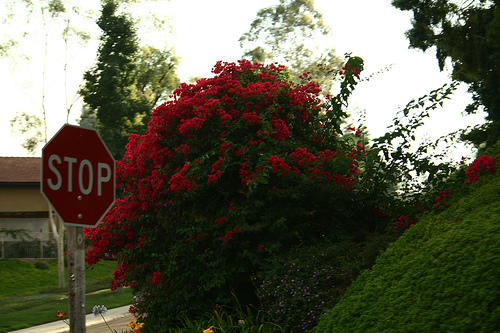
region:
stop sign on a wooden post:
[28, 114, 127, 331]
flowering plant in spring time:
[82, 43, 392, 331]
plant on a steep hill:
[90, 51, 492, 331]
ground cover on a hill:
[315, 173, 499, 331]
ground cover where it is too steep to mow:
[320, 168, 498, 328]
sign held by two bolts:
[30, 105, 127, 251]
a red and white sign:
[35, 107, 131, 327]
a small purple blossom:
[218, 235, 353, 331]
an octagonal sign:
[7, 96, 142, 331]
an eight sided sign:
[27, 102, 134, 264]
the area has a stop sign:
[28, 99, 150, 273]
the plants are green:
[337, 165, 495, 331]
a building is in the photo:
[4, 150, 61, 268]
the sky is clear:
[8, 5, 482, 79]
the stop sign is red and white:
[21, 110, 142, 256]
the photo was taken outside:
[9, 4, 487, 329]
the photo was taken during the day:
[3, 4, 494, 327]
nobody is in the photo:
[4, 7, 494, 328]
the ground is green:
[5, 257, 137, 330]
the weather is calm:
[6, 10, 485, 330]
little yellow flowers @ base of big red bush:
[122, 313, 224, 332]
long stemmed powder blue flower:
[87, 298, 127, 331]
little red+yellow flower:
[51, 307, 72, 329]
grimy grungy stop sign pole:
[66, 226, 85, 332]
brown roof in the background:
[1, 151, 59, 219]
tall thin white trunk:
[43, 27, 74, 290]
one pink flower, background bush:
[33, 231, 42, 242]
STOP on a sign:
[40, 151, 117, 196]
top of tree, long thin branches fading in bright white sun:
[33, 4, 90, 154]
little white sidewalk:
[0, 299, 146, 331]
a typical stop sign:
[23, 114, 135, 232]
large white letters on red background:
[41, 148, 123, 201]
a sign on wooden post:
[36, 118, 128, 327]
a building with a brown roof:
[0, 140, 82, 271]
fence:
[1, 214, 66, 272]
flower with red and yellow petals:
[44, 299, 84, 327]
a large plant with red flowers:
[85, 39, 384, 282]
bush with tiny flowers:
[251, 245, 357, 324]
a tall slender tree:
[10, 4, 137, 169]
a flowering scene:
[111, 62, 491, 321]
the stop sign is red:
[42, 121, 114, 229]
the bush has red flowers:
[85, 58, 495, 329]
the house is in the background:
[1, 157, 43, 252]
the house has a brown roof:
[1, 157, 41, 184]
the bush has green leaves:
[319, 178, 499, 331]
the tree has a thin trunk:
[41, 15, 86, 145]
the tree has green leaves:
[74, 0, 177, 162]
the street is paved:
[4, 305, 138, 330]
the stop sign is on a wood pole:
[65, 227, 86, 331]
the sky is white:
[3, 0, 490, 199]